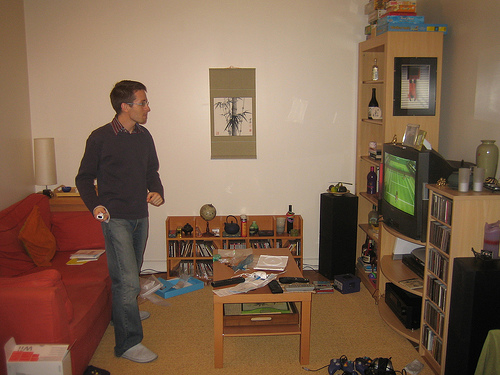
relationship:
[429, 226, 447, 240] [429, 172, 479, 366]
cd on shelf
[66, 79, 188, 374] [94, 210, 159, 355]
man wearing jeans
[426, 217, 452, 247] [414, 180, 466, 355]
cd on shelf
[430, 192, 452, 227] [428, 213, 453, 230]
cds on shelf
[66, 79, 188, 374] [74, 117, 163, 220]
man wearing sweater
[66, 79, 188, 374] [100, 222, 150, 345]
man wearing blue jeans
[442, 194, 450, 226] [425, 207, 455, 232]
cd on shelf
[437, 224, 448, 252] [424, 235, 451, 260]
cd on shelf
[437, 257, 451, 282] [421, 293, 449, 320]
cd on shelf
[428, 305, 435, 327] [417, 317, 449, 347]
cd on shelf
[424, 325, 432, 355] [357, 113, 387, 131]
cd on shelf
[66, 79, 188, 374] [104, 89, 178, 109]
man wears eyeglasses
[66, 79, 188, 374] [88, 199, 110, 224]
man holding wii controller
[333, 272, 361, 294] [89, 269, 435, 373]
gaming system on floor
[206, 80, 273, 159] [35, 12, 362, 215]
picture hanging on wall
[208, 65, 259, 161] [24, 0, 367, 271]
picture on wall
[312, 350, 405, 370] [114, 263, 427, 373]
game controls on floor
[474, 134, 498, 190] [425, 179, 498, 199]
vase on top of shelf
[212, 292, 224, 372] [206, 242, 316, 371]
leg of table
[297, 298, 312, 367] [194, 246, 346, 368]
leg of table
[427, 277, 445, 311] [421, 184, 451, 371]
cd on shelf